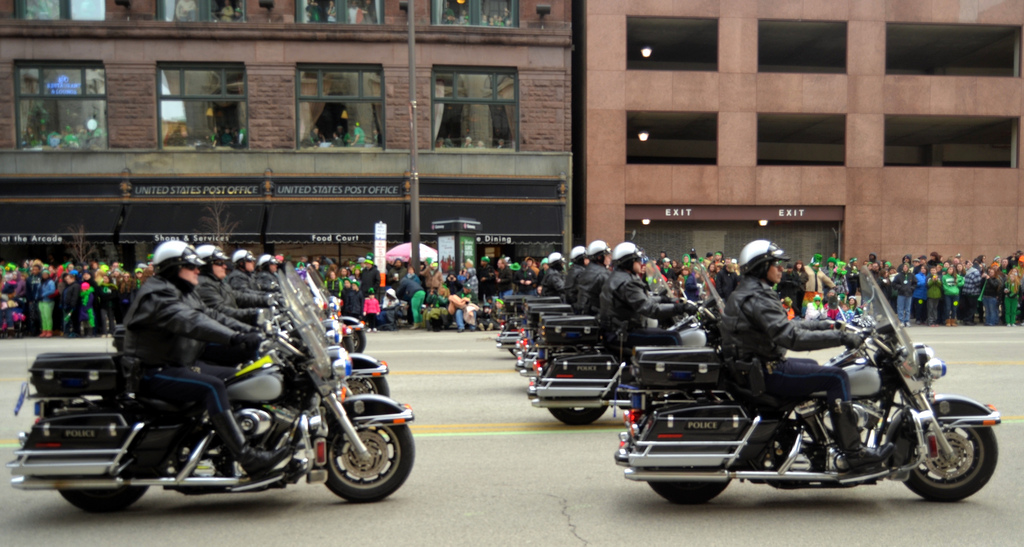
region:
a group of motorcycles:
[21, 155, 1011, 544]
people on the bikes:
[16, 198, 1001, 543]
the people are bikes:
[52, 173, 1014, 522]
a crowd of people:
[19, 228, 1022, 361]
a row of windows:
[14, 51, 593, 189]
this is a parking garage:
[558, 12, 1021, 352]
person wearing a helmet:
[131, 217, 224, 295]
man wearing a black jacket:
[86, 256, 264, 387]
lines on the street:
[368, 322, 581, 455]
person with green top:
[934, 260, 967, 296]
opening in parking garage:
[624, 12, 725, 72]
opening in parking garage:
[754, 19, 848, 75]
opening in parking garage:
[880, 19, 1019, 75]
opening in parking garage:
[624, 109, 720, 167]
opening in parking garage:
[759, 113, 846, 164]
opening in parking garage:
[887, 113, 1013, 164]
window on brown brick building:
[9, 59, 110, 153]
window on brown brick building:
[295, 61, 387, 153]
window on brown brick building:
[430, 66, 517, 151]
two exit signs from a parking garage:
[658, 202, 813, 222]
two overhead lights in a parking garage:
[633, 44, 657, 144]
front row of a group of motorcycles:
[492, 240, 1005, 506]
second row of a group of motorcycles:
[10, 237, 416, 507]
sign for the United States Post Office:
[128, 171, 262, 198]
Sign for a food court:
[310, 228, 353, 247]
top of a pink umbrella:
[387, 240, 436, 269]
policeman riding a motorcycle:
[615, 240, 1002, 506]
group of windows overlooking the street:
[7, 50, 524, 158]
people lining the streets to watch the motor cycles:
[2, 244, 1021, 324]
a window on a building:
[13, 99, 111, 150]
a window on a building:
[161, 92, 241, 149]